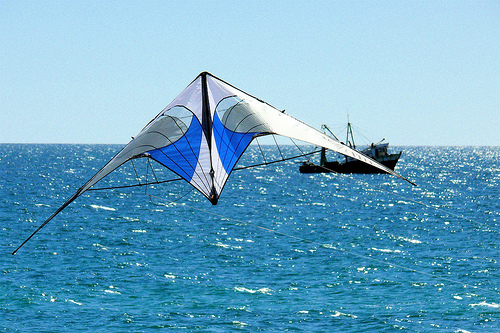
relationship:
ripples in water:
[115, 212, 271, 261] [3, 144, 497, 332]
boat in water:
[299, 108, 404, 174] [3, 144, 497, 332]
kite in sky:
[10, 72, 420, 266] [2, 2, 494, 143]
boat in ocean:
[299, 108, 404, 174] [3, 144, 497, 332]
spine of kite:
[197, 73, 229, 201] [10, 72, 420, 266]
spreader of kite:
[102, 127, 326, 190] [10, 72, 420, 266]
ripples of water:
[115, 212, 271, 261] [3, 144, 497, 332]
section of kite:
[209, 91, 252, 116] [10, 72, 420, 266]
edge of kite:
[205, 75, 267, 104] [10, 72, 420, 266]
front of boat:
[380, 152, 401, 172] [300, 136, 404, 174]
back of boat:
[297, 161, 307, 177] [300, 136, 404, 174]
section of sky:
[4, 5, 62, 32] [2, 2, 494, 143]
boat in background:
[300, 136, 404, 174] [3, 145, 496, 179]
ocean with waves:
[3, 144, 497, 332] [215, 206, 464, 305]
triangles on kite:
[147, 115, 252, 179] [10, 72, 420, 266]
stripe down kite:
[197, 73, 229, 201] [10, 72, 420, 266]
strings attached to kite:
[134, 190, 498, 297] [10, 72, 420, 266]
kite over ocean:
[10, 72, 420, 266] [3, 144, 497, 332]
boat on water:
[299, 108, 404, 174] [3, 144, 497, 332]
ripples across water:
[115, 212, 271, 261] [3, 144, 497, 332]